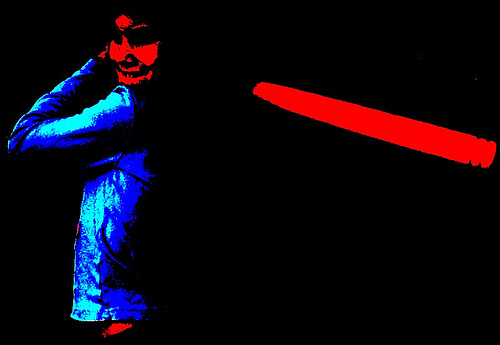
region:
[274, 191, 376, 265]
Black part of picture.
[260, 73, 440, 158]
Red light to the right.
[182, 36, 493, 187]
Red baseball bat in hands.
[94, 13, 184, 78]
Person's red face lit up.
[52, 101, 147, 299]
Blue jacket on the body.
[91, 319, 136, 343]
Red belt on person.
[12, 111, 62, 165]
Corner of right elbow.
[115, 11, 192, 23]
Hair on top of person's head.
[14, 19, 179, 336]
Person standing up with bat.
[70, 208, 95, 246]
Red button on person's jacket.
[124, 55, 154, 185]
This is a man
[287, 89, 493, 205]
This is a bat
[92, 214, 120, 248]
This is a jacket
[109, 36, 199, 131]
This is a face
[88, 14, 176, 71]
This is a head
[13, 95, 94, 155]
This is an arm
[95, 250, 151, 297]
The jacket is blue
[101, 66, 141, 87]
This is a mouth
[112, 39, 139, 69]
This is a nose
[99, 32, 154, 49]
These are dark eyes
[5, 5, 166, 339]
woman wearing blue shirt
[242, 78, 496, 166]
red lights in air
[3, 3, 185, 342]
woman wearing blue is dancing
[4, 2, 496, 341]
area is black around woman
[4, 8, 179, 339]
woman bitting her lips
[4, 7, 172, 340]
red is around her waist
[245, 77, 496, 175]
sword is red in color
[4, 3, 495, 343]
picture is glow in the dark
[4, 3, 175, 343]
woman is thin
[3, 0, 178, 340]
woman has lights in her shirt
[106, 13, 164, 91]
the red and black face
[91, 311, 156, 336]
the red part of the waist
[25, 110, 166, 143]
the person's elbow and shoulder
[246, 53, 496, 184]
the red bat being held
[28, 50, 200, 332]
the blue jacket being worn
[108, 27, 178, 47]
the black eyes of the person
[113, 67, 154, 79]
the black smile of the person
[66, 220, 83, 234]
the little bit of red on the jacket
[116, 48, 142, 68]
the nose on the face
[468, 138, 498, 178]
the end of the bat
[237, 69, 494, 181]
Red tinted bat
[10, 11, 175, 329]
Photo effects added to person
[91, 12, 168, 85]
Red faced photo effect on person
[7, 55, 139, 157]
Arm bent holding bat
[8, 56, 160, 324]
Shirt on person with blue photo effect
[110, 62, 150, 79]
Smile on person's face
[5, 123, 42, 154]
Elbow of person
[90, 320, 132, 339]
View of stomach under shirt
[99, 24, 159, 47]
Eyes blacked out by photo effect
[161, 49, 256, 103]
Bat handle invisible due to photo effect